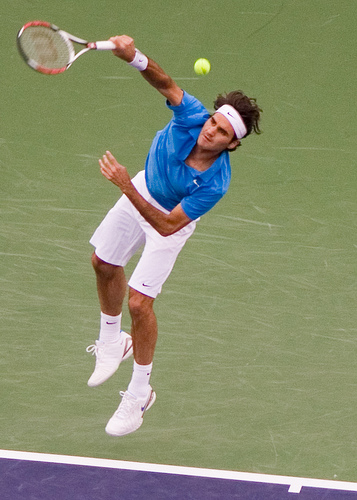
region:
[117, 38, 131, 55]
Hand in a fist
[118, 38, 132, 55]
Hand raised up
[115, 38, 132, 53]
Hand holding a racket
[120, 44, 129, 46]
The knuckles of the hand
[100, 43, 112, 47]
A white racket handle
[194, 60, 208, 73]
Tennis ball in the air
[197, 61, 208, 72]
Yellow tennis ball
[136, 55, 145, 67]
A band on the wrist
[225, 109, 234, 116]
A band on the head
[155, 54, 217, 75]
this is a tennis ball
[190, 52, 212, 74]
the ball is small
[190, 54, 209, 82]
the ball is in the air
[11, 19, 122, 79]
this is a racket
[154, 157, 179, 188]
the t-shirt is blue in color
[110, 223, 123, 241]
the short is white in color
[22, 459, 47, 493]
the area is purple in color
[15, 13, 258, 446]
the man has jumped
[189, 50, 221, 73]
a ball in air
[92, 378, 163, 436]
shoe of the person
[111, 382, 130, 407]
lace of the shoe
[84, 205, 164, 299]
a guy wearing shorts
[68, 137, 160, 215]
hand of the person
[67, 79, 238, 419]
man is on air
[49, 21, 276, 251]
man kicking the ball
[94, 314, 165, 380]
socks are white in color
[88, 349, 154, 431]
shoes are white in color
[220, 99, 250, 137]
scarf is whit in color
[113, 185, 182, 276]
short is whit in color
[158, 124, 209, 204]
t shirt is blue in color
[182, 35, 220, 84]
ball is yellow green in color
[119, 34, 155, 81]
hand scarfs is white in color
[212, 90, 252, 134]
Federer has brown hair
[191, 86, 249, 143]
black and white headband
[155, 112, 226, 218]
blue and white shirt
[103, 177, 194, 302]
man has white pants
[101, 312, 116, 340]
man has white socks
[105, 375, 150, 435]
man has white shoes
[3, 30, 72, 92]
red and white racket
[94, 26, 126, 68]
white tape on racket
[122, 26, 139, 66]
man has white wristband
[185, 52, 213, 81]
yellow ball in air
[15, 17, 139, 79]
red white and black tennis racket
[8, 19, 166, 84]
red white and black tennis racket in mans hand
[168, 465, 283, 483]
white stripe on tennis court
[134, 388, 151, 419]
blue Nike logo on white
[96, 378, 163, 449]
blue Nike logo on white shoe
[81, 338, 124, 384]
shoe laces in bow on shoe